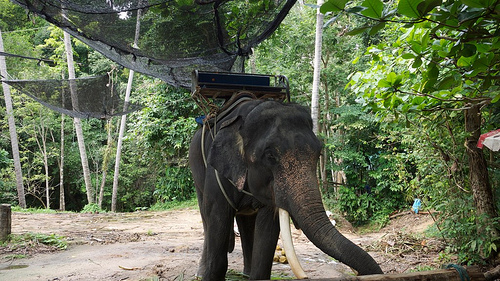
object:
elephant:
[187, 93, 384, 280]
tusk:
[277, 205, 311, 279]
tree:
[318, 0, 498, 258]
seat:
[191, 71, 294, 98]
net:
[12, 0, 297, 87]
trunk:
[282, 174, 393, 279]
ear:
[204, 114, 247, 190]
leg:
[196, 201, 232, 280]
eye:
[264, 152, 281, 163]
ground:
[0, 205, 460, 280]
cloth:
[474, 126, 499, 151]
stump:
[4, 87, 27, 207]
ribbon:
[410, 197, 422, 214]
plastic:
[447, 265, 470, 277]